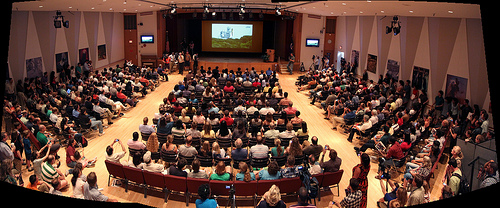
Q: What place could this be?
A: It is an auditorium.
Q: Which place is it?
A: It is an auditorium.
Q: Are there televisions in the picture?
A: Yes, there is a television.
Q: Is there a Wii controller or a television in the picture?
A: Yes, there is a television.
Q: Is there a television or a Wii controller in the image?
A: Yes, there is a television.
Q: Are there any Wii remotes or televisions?
A: Yes, there is a television.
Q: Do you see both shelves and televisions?
A: No, there is a television but no shelves.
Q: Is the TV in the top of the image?
A: Yes, the TV is in the top of the image.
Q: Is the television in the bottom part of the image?
A: No, the television is in the top of the image.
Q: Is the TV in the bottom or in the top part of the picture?
A: The TV is in the top of the image.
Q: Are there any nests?
A: No, there are no nests.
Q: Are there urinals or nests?
A: No, there are no nests or urinals.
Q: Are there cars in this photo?
A: No, there are no cars.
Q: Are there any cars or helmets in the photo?
A: No, there are no cars or helmets.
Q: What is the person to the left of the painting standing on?
A: The person is standing on the stairs.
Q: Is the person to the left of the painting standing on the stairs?
A: Yes, the person is standing on the stairs.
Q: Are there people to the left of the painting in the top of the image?
A: Yes, there is a person to the left of the painting.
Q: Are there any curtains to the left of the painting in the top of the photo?
A: No, there is a person to the left of the painting.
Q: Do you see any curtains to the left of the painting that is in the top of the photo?
A: No, there is a person to the left of the painting.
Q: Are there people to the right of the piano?
A: Yes, there is a person to the right of the piano.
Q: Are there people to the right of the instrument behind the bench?
A: Yes, there is a person to the right of the piano.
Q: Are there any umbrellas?
A: No, there are no umbrellas.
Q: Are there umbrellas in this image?
A: No, there are no umbrellas.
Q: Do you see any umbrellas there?
A: No, there are no umbrellas.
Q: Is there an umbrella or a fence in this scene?
A: No, there are no umbrellas or fences.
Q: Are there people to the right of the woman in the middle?
A: Yes, there are people to the right of the woman.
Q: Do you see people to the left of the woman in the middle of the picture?
A: No, the people are to the right of the woman.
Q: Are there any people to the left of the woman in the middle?
A: No, the people are to the right of the woman.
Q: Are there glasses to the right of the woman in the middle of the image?
A: No, there are people to the right of the woman.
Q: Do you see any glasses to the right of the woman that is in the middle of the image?
A: No, there are people to the right of the woman.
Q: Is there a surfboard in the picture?
A: No, there are no surfboards.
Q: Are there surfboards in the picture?
A: No, there are no surfboards.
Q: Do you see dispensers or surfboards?
A: No, there are no surfboards or dispensers.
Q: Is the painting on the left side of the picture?
A: No, the painting is on the right of the image.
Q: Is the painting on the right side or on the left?
A: The painting is on the right of the image.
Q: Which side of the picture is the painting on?
A: The painting is on the right of the image.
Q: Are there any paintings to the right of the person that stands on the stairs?
A: Yes, there is a painting to the right of the person.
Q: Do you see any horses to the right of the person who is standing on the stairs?
A: No, there is a painting to the right of the person.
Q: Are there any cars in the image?
A: No, there are no cars.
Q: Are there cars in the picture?
A: No, there are no cars.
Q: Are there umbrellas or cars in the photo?
A: No, there are no cars or umbrellas.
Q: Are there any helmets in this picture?
A: No, there are no helmets.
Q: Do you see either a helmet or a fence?
A: No, there are no helmets or fences.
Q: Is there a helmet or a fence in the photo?
A: No, there are no helmets or fences.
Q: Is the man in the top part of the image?
A: No, the man is in the bottom of the image.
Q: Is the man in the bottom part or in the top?
A: The man is in the bottom of the image.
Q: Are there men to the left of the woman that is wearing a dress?
A: Yes, there is a man to the left of the woman.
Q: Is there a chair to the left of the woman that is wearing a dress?
A: No, there is a man to the left of the woman.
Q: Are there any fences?
A: No, there are no fences.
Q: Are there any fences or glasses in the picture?
A: No, there are no fences or glasses.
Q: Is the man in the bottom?
A: Yes, the man is in the bottom of the image.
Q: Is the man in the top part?
A: No, the man is in the bottom of the image.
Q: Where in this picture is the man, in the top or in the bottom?
A: The man is in the bottom of the image.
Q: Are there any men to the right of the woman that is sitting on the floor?
A: Yes, there is a man to the right of the woman.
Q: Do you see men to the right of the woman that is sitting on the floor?
A: Yes, there is a man to the right of the woman.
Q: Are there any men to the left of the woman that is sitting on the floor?
A: No, the man is to the right of the woman.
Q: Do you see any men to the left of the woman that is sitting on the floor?
A: No, the man is to the right of the woman.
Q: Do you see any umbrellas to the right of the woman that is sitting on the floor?
A: No, there is a man to the right of the woman.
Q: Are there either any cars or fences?
A: No, there are no cars or fences.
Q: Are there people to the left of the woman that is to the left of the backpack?
A: Yes, there are people to the left of the woman.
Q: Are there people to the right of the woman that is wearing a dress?
A: No, the people are to the left of the woman.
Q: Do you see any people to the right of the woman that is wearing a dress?
A: No, the people are to the left of the woman.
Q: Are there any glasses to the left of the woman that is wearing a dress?
A: No, there are people to the left of the woman.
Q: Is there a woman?
A: Yes, there is a woman.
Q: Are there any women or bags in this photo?
A: Yes, there is a woman.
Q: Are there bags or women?
A: Yes, there is a woman.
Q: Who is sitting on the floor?
A: The woman is sitting on the floor.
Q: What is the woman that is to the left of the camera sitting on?
A: The woman is sitting on the floor.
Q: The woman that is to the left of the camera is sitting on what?
A: The woman is sitting on the floor.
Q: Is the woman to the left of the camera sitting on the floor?
A: Yes, the woman is sitting on the floor.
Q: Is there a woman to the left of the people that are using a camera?
A: Yes, there is a woman to the left of the people.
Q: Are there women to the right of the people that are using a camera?
A: No, the woman is to the left of the people.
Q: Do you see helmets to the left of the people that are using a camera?
A: No, there is a woman to the left of the people.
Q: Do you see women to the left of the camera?
A: Yes, there is a woman to the left of the camera.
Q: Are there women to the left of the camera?
A: Yes, there is a woman to the left of the camera.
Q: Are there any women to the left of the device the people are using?
A: Yes, there is a woman to the left of the camera.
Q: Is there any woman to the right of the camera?
A: No, the woman is to the left of the camera.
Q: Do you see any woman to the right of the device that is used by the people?
A: No, the woman is to the left of the camera.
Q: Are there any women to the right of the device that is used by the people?
A: No, the woman is to the left of the camera.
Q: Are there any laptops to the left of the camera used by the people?
A: No, there is a woman to the left of the camera.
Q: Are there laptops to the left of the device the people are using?
A: No, there is a woman to the left of the camera.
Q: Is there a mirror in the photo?
A: No, there are no mirrors.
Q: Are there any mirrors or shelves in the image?
A: No, there are no mirrors or shelves.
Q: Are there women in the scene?
A: Yes, there is a woman.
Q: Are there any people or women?
A: Yes, there is a woman.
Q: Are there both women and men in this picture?
A: Yes, there are both a woman and a man.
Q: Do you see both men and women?
A: Yes, there are both a woman and a man.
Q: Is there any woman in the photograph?
A: Yes, there is a woman.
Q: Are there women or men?
A: Yes, there is a woman.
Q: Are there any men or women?
A: Yes, there is a woman.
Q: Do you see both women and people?
A: Yes, there are both a woman and a person.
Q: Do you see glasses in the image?
A: No, there are no glasses.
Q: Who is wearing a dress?
A: The woman is wearing a dress.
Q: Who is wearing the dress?
A: The woman is wearing a dress.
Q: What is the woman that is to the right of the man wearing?
A: The woman is wearing a dress.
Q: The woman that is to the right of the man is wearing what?
A: The woman is wearing a dress.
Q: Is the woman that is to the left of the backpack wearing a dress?
A: Yes, the woman is wearing a dress.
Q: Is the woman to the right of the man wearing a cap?
A: No, the woman is wearing a dress.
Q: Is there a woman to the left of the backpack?
A: Yes, there is a woman to the left of the backpack.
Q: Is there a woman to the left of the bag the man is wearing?
A: Yes, there is a woman to the left of the backpack.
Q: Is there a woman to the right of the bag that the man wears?
A: No, the woman is to the left of the backpack.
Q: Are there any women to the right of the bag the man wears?
A: No, the woman is to the left of the backpack.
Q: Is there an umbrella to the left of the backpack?
A: No, there is a woman to the left of the backpack.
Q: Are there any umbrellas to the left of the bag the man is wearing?
A: No, there is a woman to the left of the backpack.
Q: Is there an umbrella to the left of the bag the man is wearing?
A: No, there is a woman to the left of the backpack.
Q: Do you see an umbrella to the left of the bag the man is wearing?
A: No, there is a woman to the left of the backpack.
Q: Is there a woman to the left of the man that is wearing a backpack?
A: Yes, there is a woman to the left of the man.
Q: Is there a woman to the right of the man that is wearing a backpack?
A: No, the woman is to the left of the man.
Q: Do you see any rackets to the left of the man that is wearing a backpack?
A: No, there is a woman to the left of the man.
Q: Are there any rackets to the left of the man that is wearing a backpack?
A: No, there is a woman to the left of the man.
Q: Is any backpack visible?
A: Yes, there is a backpack.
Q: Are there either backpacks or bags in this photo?
A: Yes, there is a backpack.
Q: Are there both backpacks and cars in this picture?
A: No, there is a backpack but no cars.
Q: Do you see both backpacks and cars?
A: No, there is a backpack but no cars.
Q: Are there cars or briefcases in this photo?
A: No, there are no cars or briefcases.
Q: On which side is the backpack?
A: The backpack is on the right of the image.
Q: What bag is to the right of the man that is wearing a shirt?
A: The bag is a backpack.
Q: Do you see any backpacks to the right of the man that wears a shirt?
A: Yes, there is a backpack to the right of the man.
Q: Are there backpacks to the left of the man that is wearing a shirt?
A: No, the backpack is to the right of the man.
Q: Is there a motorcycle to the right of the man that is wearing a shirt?
A: No, there is a backpack to the right of the man.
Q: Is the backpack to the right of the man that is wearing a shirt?
A: Yes, the backpack is to the right of the man.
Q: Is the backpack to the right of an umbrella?
A: No, the backpack is to the right of the man.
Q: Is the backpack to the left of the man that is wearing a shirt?
A: No, the backpack is to the right of the man.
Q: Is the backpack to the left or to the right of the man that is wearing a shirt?
A: The backpack is to the right of the man.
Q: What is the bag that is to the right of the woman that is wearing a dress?
A: The bag is a backpack.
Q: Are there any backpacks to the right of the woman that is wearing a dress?
A: Yes, there is a backpack to the right of the woman.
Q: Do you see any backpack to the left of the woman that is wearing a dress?
A: No, the backpack is to the right of the woman.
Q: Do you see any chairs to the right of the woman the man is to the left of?
A: No, there is a backpack to the right of the woman.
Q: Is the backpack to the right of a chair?
A: No, the backpack is to the right of a woman.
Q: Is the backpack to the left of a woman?
A: No, the backpack is to the right of a woman.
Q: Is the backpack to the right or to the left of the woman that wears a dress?
A: The backpack is to the right of the woman.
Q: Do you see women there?
A: Yes, there is a woman.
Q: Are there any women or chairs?
A: Yes, there is a woman.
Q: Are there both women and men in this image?
A: Yes, there are both a woman and a man.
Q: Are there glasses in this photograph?
A: No, there are no glasses.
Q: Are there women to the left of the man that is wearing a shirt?
A: Yes, there is a woman to the left of the man.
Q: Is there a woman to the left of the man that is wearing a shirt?
A: Yes, there is a woman to the left of the man.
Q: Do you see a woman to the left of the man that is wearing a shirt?
A: Yes, there is a woman to the left of the man.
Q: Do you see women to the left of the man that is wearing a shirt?
A: Yes, there is a woman to the left of the man.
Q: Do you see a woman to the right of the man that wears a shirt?
A: No, the woman is to the left of the man.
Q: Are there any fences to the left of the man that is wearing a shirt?
A: No, there is a woman to the left of the man.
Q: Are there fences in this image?
A: No, there are no fences.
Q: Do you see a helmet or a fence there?
A: No, there are no fences or helmets.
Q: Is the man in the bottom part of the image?
A: Yes, the man is in the bottom of the image.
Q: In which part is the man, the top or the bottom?
A: The man is in the bottom of the image.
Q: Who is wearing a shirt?
A: The man is wearing a shirt.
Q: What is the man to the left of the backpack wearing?
A: The man is wearing a shirt.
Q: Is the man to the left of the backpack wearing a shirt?
A: Yes, the man is wearing a shirt.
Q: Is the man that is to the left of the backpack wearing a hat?
A: No, the man is wearing a shirt.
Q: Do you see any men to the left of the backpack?
A: Yes, there is a man to the left of the backpack.